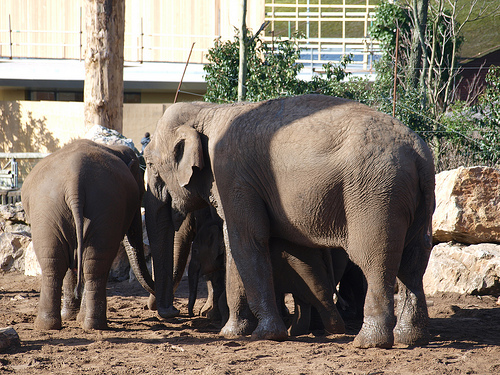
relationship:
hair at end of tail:
[70, 278, 83, 299] [62, 199, 89, 304]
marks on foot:
[360, 317, 387, 333] [331, 302, 408, 359]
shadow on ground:
[415, 300, 499, 355] [2, 268, 499, 368]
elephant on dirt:
[136, 93, 441, 351] [117, 332, 159, 369]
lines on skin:
[347, 150, 389, 206] [211, 102, 403, 320]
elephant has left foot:
[136, 93, 457, 358] [351, 306, 396, 350]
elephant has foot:
[136, 93, 457, 358] [376, 314, 445, 344]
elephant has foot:
[136, 93, 441, 351] [255, 277, 298, 340]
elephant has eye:
[136, 93, 457, 358] [145, 156, 155, 172]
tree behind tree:
[207, 29, 301, 104] [368, 0, 411, 109]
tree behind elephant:
[207, 29, 301, 104] [18, 140, 152, 333]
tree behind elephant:
[207, 29, 301, 104] [136, 93, 441, 351]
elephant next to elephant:
[18, 140, 152, 333] [136, 93, 441, 351]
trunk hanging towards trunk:
[118, 198, 157, 303] [138, 157, 183, 322]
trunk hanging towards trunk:
[118, 198, 157, 303] [182, 237, 204, 321]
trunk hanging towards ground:
[118, 198, 157, 303] [2, 268, 499, 368]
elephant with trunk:
[136, 93, 441, 351] [147, 186, 181, 321]